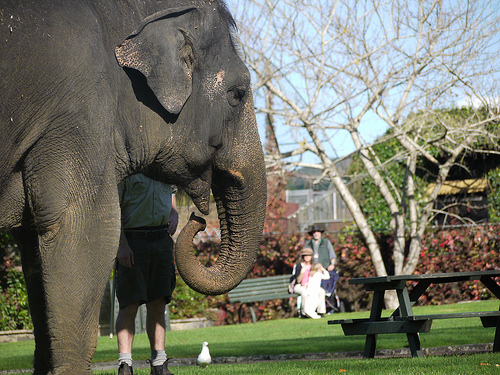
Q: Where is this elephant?
A: Park.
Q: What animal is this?
A: Elephant.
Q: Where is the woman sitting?
A: Bench.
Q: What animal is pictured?
A: Elephant.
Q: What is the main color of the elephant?
A: Gray.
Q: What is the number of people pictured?
A: 3.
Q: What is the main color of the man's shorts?
A: Black.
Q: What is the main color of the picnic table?
A: Black.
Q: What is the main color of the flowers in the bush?
A: Red.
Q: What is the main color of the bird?
A: White.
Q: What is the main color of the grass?
A: Green.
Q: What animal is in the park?
A: Elephant.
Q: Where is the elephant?
A: In the park.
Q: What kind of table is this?
A: Picnic.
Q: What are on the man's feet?
A: Black shoes.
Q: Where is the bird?
A: Under the elephant's trunk.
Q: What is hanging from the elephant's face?
A: A trunk.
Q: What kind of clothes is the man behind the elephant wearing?
A: Shorts.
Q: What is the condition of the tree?
A: Leafless.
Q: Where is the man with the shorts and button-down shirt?
A: On the far side of the elephant.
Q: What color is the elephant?
A: Grey.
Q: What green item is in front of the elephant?
A: A picnic table.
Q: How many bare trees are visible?
A: One.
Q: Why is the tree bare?
A: Its leaves have all fallen off.